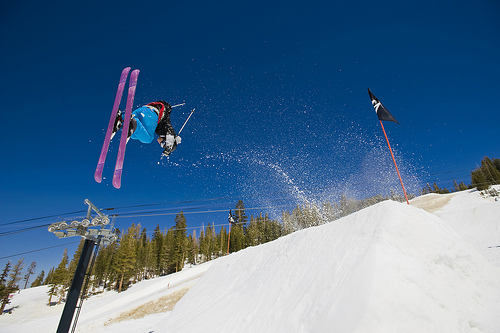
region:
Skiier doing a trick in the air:
[90, 65, 199, 198]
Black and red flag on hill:
[363, 84, 416, 205]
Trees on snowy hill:
[116, 201, 211, 278]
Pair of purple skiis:
[93, 65, 140, 190]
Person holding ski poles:
[92, 63, 197, 197]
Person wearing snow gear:
[93, 64, 197, 191]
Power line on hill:
[40, 196, 116, 332]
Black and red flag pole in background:
[221, 206, 238, 261]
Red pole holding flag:
[373, 118, 413, 205]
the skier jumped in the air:
[52, 36, 242, 198]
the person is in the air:
[87, 40, 212, 200]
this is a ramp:
[138, 183, 497, 328]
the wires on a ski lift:
[0, 144, 497, 249]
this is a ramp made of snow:
[143, 176, 493, 331]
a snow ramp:
[158, 191, 498, 329]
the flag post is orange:
[351, 70, 424, 215]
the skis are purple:
[92, 35, 147, 207]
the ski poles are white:
[168, 73, 202, 147]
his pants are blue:
[120, 95, 167, 155]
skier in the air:
[50, 55, 208, 204]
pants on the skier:
[134, 105, 162, 152]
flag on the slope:
[357, 68, 419, 214]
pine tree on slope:
[169, 208, 187, 268]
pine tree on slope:
[113, 225, 140, 297]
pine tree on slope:
[136, 235, 156, 278]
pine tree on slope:
[233, 207, 257, 250]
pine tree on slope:
[461, 150, 492, 190]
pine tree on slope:
[260, 220, 275, 247]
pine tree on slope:
[222, 230, 233, 266]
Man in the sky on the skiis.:
[99, 45, 195, 187]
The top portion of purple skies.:
[100, 50, 140, 90]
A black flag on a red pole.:
[345, 72, 415, 124]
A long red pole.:
[360, 120, 426, 200]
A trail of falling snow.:
[225, 131, 315, 213]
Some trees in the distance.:
[465, 147, 495, 184]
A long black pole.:
[30, 225, 95, 327]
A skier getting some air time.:
[16, 48, 226, 220]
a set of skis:
[84, 45, 144, 192]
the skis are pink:
[86, 51, 145, 194]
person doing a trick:
[72, 35, 212, 200]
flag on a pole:
[360, 89, 429, 206]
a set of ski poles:
[151, 87, 203, 157]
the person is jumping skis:
[85, 60, 254, 220]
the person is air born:
[64, 47, 201, 139]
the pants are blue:
[133, 88, 169, 140]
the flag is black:
[360, 92, 405, 135]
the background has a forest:
[112, 201, 321, 301]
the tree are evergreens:
[103, 218, 173, 243]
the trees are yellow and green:
[100, 201, 262, 307]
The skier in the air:
[81, 50, 206, 199]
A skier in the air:
[85, 62, 205, 194]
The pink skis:
[94, 57, 146, 197]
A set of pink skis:
[91, 62, 145, 199]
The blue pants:
[123, 101, 162, 148]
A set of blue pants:
[128, 106, 158, 142]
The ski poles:
[162, 99, 201, 135]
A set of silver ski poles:
[162, 92, 203, 140]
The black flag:
[360, 85, 402, 125]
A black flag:
[364, 86, 401, 122]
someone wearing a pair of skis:
[93, 64, 194, 189]